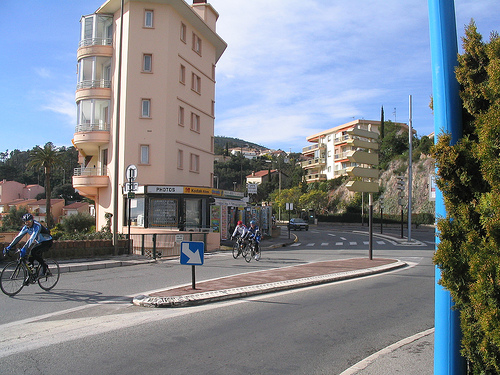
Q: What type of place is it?
A: It is a city.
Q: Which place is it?
A: It is a city.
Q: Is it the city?
A: Yes, it is the city.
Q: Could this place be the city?
A: Yes, it is the city.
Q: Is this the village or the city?
A: It is the city.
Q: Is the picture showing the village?
A: No, the picture is showing the city.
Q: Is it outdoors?
A: Yes, it is outdoors.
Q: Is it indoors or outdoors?
A: It is outdoors.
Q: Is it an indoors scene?
A: No, it is outdoors.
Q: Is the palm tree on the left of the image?
A: Yes, the palm tree is on the left of the image.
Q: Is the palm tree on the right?
A: No, the palm tree is on the left of the image.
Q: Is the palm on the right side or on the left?
A: The palm is on the left of the image.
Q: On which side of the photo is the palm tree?
A: The palm tree is on the left of the image.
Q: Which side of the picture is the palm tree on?
A: The palm tree is on the left of the image.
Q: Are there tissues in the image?
A: No, there are no tissues.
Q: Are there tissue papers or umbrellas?
A: No, there are no tissue papers or umbrellas.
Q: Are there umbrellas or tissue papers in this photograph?
A: No, there are no tissue papers or umbrellas.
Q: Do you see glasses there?
A: No, there are no glasses.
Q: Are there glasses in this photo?
A: No, there are no glasses.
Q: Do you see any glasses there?
A: No, there are no glasses.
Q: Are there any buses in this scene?
A: No, there are no buses.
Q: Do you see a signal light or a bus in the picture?
A: No, there are no buses or traffic lights.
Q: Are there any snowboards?
A: No, there are no snowboards.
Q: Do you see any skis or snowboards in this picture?
A: No, there are no snowboards or skis.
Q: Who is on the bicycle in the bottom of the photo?
A: The man is on the bicycle.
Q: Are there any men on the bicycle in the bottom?
A: Yes, there is a man on the bicycle.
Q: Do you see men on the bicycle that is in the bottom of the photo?
A: Yes, there is a man on the bicycle.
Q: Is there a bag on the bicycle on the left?
A: No, there is a man on the bicycle.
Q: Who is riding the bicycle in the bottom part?
A: The man is riding the bicycle.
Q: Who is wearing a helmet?
A: The man is wearing a helmet.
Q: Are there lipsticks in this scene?
A: No, there are no lipsticks.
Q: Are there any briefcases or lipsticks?
A: No, there are no lipsticks or briefcases.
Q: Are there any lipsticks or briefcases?
A: No, there are no lipsticks or briefcases.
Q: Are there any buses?
A: No, there are no buses.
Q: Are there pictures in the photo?
A: No, there are no pictures.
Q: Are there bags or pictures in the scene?
A: No, there are no pictures or bags.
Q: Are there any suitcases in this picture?
A: No, there are no suitcases.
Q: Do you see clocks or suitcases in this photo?
A: No, there are no suitcases or clocks.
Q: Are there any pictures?
A: No, there are no pictures.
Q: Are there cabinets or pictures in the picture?
A: No, there are no pictures or cabinets.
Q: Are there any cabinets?
A: No, there are no cabinets.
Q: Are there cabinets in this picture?
A: No, there are no cabinets.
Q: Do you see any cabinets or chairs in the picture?
A: No, there are no cabinets or chairs.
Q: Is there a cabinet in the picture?
A: No, there are no cabinets.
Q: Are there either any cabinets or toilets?
A: No, there are no cabinets or toilets.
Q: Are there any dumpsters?
A: No, there are no dumpsters.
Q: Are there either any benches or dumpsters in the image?
A: No, there are no dumpsters or benches.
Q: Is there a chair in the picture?
A: No, there are no chairs.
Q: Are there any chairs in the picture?
A: No, there are no chairs.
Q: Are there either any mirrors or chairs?
A: No, there are no chairs or mirrors.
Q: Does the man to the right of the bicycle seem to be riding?
A: Yes, the man is riding.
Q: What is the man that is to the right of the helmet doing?
A: The man is riding.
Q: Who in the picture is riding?
A: The man is riding.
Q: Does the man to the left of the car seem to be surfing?
A: No, the man is riding.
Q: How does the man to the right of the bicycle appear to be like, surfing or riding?
A: The man is riding.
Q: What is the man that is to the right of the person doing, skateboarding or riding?
A: The man is riding.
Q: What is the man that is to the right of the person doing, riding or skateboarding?
A: The man is riding.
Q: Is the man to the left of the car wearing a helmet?
A: Yes, the man is wearing a helmet.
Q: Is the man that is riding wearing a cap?
A: No, the man is wearing a helmet.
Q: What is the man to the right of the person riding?
A: The man is riding the bicycle.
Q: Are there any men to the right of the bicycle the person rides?
A: Yes, there is a man to the right of the bicycle.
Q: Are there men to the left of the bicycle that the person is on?
A: No, the man is to the right of the bicycle.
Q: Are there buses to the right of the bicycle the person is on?
A: No, there is a man to the right of the bicycle.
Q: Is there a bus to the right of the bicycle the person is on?
A: No, there is a man to the right of the bicycle.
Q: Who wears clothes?
A: The man wears clothes.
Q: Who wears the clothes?
A: The man wears clothes.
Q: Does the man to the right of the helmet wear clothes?
A: Yes, the man wears clothes.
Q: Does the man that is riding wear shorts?
A: No, the man wears clothes.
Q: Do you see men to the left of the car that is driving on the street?
A: Yes, there is a man to the left of the car.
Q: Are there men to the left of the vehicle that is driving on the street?
A: Yes, there is a man to the left of the car.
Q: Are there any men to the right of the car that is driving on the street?
A: No, the man is to the left of the car.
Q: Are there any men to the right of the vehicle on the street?
A: No, the man is to the left of the car.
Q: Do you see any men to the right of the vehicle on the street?
A: No, the man is to the left of the car.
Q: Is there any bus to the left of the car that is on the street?
A: No, there is a man to the left of the car.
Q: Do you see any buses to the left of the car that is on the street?
A: No, there is a man to the left of the car.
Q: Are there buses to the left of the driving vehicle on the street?
A: No, there is a man to the left of the car.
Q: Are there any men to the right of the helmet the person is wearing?
A: Yes, there is a man to the right of the helmet.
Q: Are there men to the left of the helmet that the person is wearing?
A: No, the man is to the right of the helmet.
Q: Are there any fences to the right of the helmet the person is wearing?
A: No, there is a man to the right of the helmet.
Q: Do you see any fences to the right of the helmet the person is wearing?
A: No, there is a man to the right of the helmet.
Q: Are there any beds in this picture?
A: No, there are no beds.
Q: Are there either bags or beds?
A: No, there are no beds or bags.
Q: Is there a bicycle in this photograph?
A: Yes, there is a bicycle.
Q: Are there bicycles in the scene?
A: Yes, there is a bicycle.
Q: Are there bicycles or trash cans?
A: Yes, there is a bicycle.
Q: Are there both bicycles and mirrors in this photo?
A: No, there is a bicycle but no mirrors.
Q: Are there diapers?
A: No, there are no diapers.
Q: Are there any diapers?
A: No, there are no diapers.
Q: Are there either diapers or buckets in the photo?
A: No, there are no diapers or buckets.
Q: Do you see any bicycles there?
A: Yes, there is a bicycle.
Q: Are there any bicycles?
A: Yes, there is a bicycle.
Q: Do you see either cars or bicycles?
A: Yes, there is a bicycle.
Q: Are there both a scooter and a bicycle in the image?
A: No, there is a bicycle but no scooters.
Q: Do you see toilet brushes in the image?
A: No, there are no toilet brushes.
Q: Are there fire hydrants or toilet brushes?
A: No, there are no toilet brushes or fire hydrants.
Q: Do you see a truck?
A: No, there are no trucks.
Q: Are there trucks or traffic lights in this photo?
A: No, there are no trucks or traffic lights.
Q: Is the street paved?
A: Yes, the street is paved.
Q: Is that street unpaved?
A: No, the street is paved.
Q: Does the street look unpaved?
A: No, the street is paved.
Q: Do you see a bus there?
A: No, there are no buses.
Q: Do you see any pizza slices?
A: No, there are no pizza slices.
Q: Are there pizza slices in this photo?
A: No, there are no pizza slices.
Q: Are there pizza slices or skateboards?
A: No, there are no pizza slices or skateboards.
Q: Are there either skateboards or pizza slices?
A: No, there are no pizza slices or skateboards.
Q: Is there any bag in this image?
A: No, there are no bags.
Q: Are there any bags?
A: No, there are no bags.